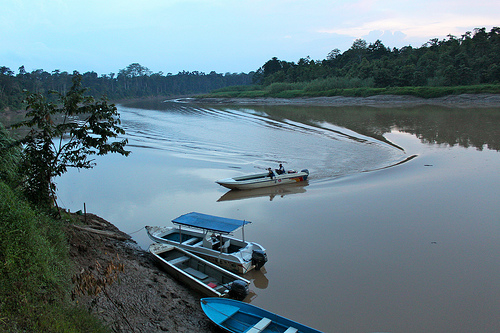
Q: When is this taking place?
A: Daytime.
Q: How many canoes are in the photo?
A: Four.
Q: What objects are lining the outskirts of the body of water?
A: Trees and foliage.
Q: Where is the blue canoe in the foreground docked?
A: Mud.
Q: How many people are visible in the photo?
A: One.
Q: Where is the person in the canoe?
A: Body of water.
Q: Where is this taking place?
A: In a lake.